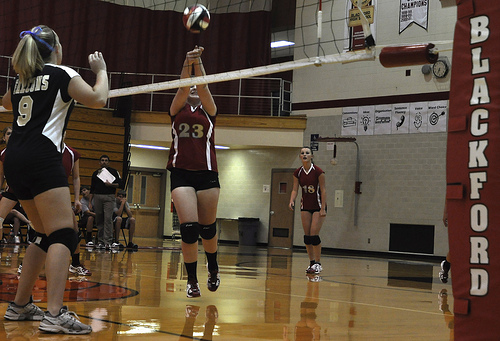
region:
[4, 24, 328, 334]
three girls in a school basketball game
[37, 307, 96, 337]
light colored sneaker planted firmly on the gym floor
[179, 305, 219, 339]
shadow on the floor of two legs and sneakers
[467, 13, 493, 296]
Blackford written in white on a red background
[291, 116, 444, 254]
gray cement brick wall behind player 18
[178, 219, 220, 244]
black knee pads on player 23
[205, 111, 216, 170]
white stripe on player 23's shirt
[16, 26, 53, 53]
blue ribbon in player 9's hair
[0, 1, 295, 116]
maroon curtains above the seating for the spectators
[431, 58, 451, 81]
round black and white clock on the wall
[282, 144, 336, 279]
teen girl in volleyball uniform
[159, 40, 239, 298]
teen girl playing volleyball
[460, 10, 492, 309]
BLACKFORD in black and white letters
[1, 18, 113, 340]
teen girl in black and white uniform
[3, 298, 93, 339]
ladies white athletic foot wear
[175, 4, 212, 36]
red white blue volleyball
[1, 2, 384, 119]
volleyball net between players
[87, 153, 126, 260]
man on sidelines with clipboard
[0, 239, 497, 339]
shiny wood gym floor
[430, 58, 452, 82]
round clock on distant wall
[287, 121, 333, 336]
Girl standing on the court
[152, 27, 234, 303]
Girl standing on the court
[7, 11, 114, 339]
Girl standing on the court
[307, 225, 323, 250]
Small black knee pad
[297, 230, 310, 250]
Small black knee pad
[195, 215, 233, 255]
Small black knee pad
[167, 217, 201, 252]
Small black knee pad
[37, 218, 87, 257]
Small black knee pad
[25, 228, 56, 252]
Small black knee pad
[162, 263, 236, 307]
Red and black shoes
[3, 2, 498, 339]
girls volleyball match at Blackford gym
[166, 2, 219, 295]
volleyball player setting the ball for another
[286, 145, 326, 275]
volleyball player in black shorts and red and white top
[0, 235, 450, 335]
polished wood gym floor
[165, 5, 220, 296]
volleyball player leaves her feet to make a play on the ball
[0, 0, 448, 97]
black volleyball net with white edge tape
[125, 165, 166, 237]
doors to gym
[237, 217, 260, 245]
metal trash receptacle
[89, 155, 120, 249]
volleyball coach watching match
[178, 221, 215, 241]
volleyball knee pads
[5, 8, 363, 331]
females playing volleyball on court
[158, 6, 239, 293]
female hitting ball with hands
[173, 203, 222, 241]
knee pads on player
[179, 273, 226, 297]
athletic sneakers on player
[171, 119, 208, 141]
athletic top uniform on player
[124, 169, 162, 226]
double doors to gym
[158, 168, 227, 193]
shorts on the player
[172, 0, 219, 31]
volleyball in the game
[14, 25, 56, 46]
ribbon in female's hair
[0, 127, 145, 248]
spectators on the side